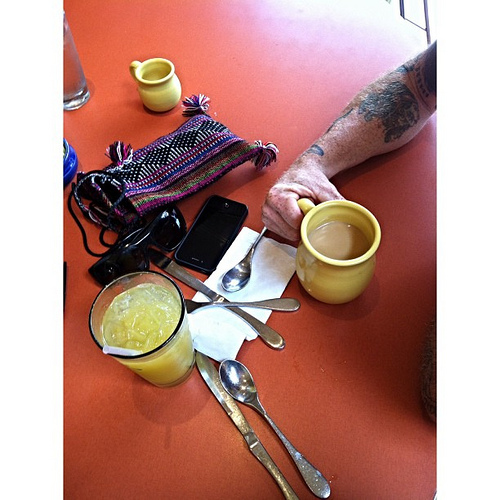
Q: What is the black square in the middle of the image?
A: A phone.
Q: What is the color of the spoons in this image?
A: Silver.